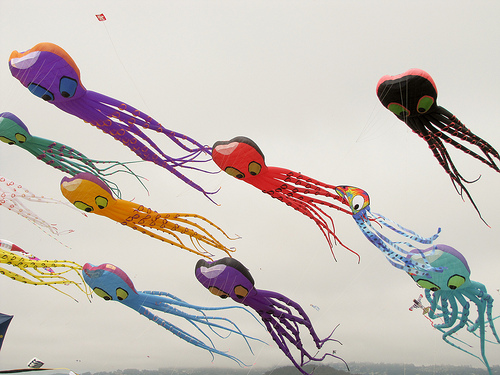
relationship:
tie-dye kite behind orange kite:
[333, 182, 445, 274] [208, 125, 363, 260]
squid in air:
[208, 137, 365, 264] [0, 1, 495, 368]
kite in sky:
[9, 42, 222, 202] [0, 0, 498, 373]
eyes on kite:
[93, 187, 123, 220] [67, 159, 232, 250]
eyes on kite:
[74, 190, 93, 212] [67, 159, 232, 250]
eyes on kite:
[25, 75, 81, 102] [9, 42, 222, 202]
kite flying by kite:
[1, 115, 161, 202] [405, 244, 499, 373]